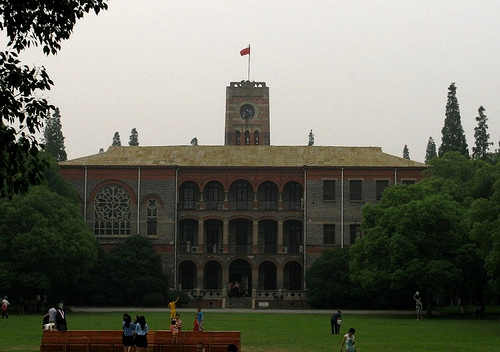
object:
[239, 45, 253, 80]
flag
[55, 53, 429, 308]
building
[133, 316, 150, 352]
girl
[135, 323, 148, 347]
uniform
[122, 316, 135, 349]
girl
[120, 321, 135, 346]
uniform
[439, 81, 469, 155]
tree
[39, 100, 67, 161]
tree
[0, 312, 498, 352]
grass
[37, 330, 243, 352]
bench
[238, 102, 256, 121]
clock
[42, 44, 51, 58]
leaf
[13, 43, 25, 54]
leaf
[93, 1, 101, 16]
leaf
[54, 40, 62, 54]
leaf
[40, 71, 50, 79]
leaf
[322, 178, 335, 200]
window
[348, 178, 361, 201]
window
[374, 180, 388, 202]
window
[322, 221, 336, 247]
window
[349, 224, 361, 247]
window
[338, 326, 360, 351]
person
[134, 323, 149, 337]
top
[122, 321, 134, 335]
top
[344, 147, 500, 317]
tree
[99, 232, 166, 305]
tree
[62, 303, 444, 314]
side walk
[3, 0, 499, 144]
sky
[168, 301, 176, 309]
shirt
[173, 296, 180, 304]
arm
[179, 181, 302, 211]
balcony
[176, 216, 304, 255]
balcony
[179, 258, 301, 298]
balcony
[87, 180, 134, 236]
window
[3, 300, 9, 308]
t-shirt